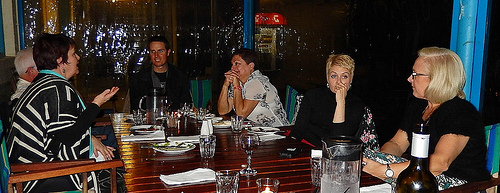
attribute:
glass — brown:
[210, 165, 240, 191]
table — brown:
[110, 102, 389, 191]